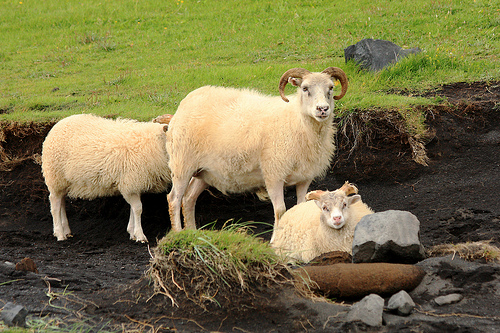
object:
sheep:
[38, 111, 170, 245]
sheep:
[162, 67, 350, 254]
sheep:
[268, 180, 377, 266]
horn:
[278, 68, 302, 102]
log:
[293, 262, 423, 301]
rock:
[339, 36, 418, 76]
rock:
[350, 208, 427, 263]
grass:
[179, 230, 242, 253]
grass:
[54, 32, 97, 61]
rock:
[0, 302, 29, 330]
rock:
[344, 291, 385, 328]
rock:
[387, 289, 417, 316]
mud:
[94, 248, 112, 266]